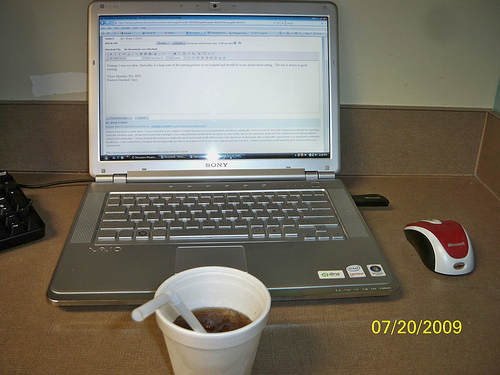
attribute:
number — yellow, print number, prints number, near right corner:
[370, 318, 463, 338]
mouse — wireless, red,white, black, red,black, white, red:
[403, 217, 477, 276]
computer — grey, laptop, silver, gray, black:
[46, 3, 402, 308]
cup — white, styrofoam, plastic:
[151, 264, 271, 374]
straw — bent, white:
[130, 291, 210, 336]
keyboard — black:
[0, 173, 46, 252]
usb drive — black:
[350, 194, 388, 206]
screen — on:
[99, 14, 331, 156]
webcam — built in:
[209, 0, 219, 10]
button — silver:
[97, 230, 117, 240]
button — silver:
[134, 230, 150, 240]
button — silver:
[248, 225, 266, 237]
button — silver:
[266, 226, 282, 237]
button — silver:
[283, 226, 298, 235]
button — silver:
[98, 220, 137, 229]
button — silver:
[136, 221, 152, 229]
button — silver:
[154, 221, 167, 230]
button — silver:
[170, 220, 184, 230]